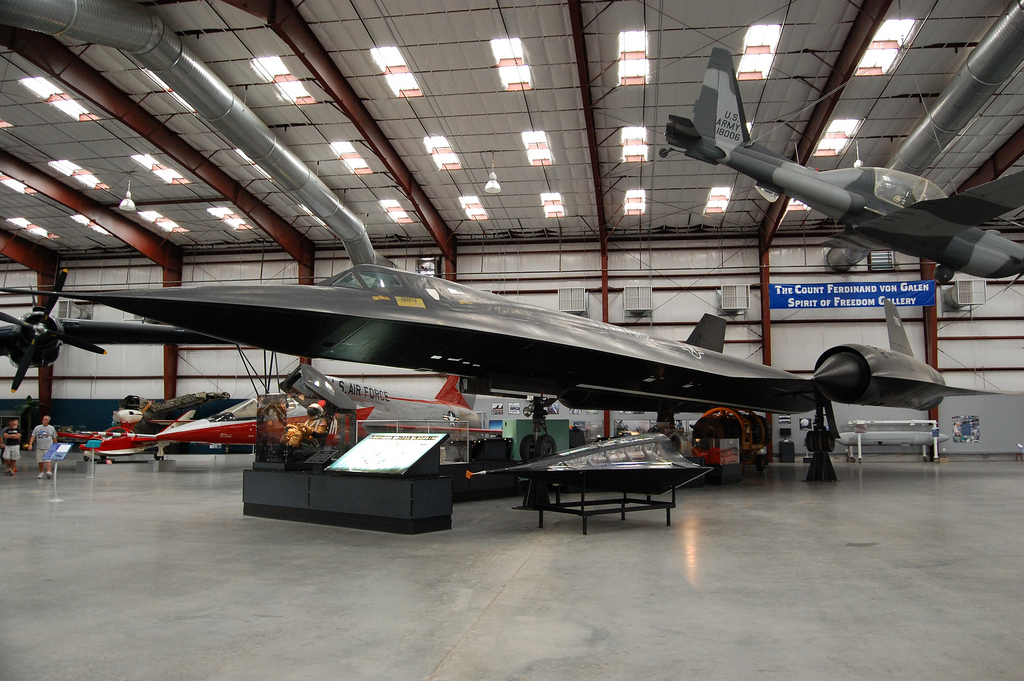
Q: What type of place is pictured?
A: It is a hangar.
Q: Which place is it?
A: It is a hangar.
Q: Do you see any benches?
A: No, there are no benches.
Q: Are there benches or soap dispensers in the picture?
A: No, there are no benches or soap dispensers.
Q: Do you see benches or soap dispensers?
A: No, there are no benches or soap dispensers.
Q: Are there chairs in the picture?
A: No, there are no chairs.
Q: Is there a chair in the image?
A: No, there are no chairs.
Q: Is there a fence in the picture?
A: No, there are no fences.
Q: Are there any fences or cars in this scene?
A: No, there are no fences or cars.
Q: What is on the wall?
A: The sign is on the wall.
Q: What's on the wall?
A: The sign is on the wall.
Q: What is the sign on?
A: The sign is on the wall.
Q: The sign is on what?
A: The sign is on the wall.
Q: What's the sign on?
A: The sign is on the wall.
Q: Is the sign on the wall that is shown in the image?
A: Yes, the sign is on the wall.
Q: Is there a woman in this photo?
A: No, there are no women.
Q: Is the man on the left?
A: Yes, the man is on the left of the image.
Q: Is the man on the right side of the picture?
A: No, the man is on the left of the image.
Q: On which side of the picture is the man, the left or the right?
A: The man is on the left of the image.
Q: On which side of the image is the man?
A: The man is on the left of the image.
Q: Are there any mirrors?
A: No, there are no mirrors.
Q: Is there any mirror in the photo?
A: No, there are no mirrors.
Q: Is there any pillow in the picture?
A: No, there are no pillows.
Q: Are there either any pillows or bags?
A: No, there are no pillows or bags.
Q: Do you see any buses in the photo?
A: No, there are no buses.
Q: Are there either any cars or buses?
A: No, there are no buses or cars.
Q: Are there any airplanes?
A: Yes, there is an airplane.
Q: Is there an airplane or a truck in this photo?
A: Yes, there is an airplane.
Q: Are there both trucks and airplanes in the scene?
A: No, there is an airplane but no trucks.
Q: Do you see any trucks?
A: No, there are no trucks.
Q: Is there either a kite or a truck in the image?
A: No, there are no trucks or kites.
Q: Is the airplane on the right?
A: Yes, the airplane is on the right of the image.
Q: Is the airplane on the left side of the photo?
A: No, the airplane is on the right of the image.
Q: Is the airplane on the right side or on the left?
A: The airplane is on the right of the image.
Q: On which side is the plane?
A: The plane is on the right of the image.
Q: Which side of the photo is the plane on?
A: The plane is on the right of the image.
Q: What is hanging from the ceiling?
A: The plane is hanging from the ceiling.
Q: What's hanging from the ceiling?
A: The plane is hanging from the ceiling.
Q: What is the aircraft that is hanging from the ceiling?
A: The aircraft is an airplane.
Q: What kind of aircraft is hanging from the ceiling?
A: The aircraft is an airplane.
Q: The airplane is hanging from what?
A: The airplane is hanging from the ceiling.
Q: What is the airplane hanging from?
A: The airplane is hanging from the ceiling.